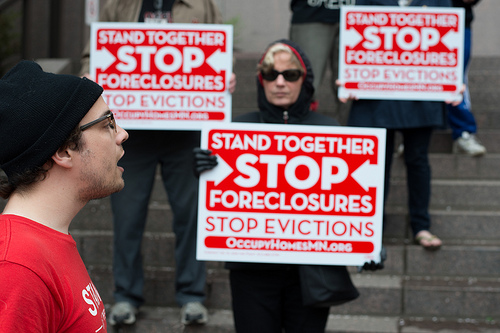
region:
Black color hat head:
[10, 65, 97, 132]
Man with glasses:
[39, 108, 136, 218]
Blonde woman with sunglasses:
[248, 43, 322, 121]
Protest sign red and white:
[202, 131, 394, 271]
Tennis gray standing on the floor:
[103, 297, 209, 322]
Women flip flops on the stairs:
[392, 216, 454, 255]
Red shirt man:
[0, 210, 110, 327]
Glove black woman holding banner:
[187, 139, 224, 191]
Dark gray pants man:
[110, 152, 200, 297]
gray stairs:
[364, 262, 497, 332]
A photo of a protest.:
[1, 0, 499, 332]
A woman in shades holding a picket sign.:
[196, 38, 388, 330]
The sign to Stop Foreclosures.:
[208, 155, 375, 242]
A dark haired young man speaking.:
[1, 60, 127, 332]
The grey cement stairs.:
[443, 197, 495, 330]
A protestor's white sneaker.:
[447, 128, 494, 167]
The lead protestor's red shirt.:
[1, 215, 123, 330]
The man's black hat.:
[2, 58, 100, 175]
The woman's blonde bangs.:
[260, 41, 295, 68]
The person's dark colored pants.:
[113, 130, 205, 330]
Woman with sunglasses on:
[241, 46, 311, 98]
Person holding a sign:
[186, 115, 458, 289]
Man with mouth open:
[55, 105, 169, 200]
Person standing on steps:
[88, 256, 220, 332]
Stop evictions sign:
[200, 192, 380, 275]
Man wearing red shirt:
[6, 203, 146, 325]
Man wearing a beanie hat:
[3, 93, 178, 206]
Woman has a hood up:
[241, 37, 354, 156]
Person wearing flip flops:
[398, 196, 463, 261]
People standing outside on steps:
[11, 61, 496, 298]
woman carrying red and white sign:
[202, 48, 397, 256]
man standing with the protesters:
[2, 62, 144, 332]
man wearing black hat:
[2, 63, 119, 331]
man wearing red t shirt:
[0, 194, 116, 328]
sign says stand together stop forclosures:
[201, 118, 391, 270]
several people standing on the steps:
[91, 3, 493, 326]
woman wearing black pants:
[206, 236, 389, 327]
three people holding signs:
[82, 14, 464, 326]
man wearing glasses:
[85, 103, 127, 138]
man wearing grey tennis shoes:
[103, 274, 216, 328]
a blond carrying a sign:
[187, 42, 392, 332]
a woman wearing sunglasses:
[190, 40, 387, 332]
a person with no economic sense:
[192, 39, 389, 331]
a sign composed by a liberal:
[197, 123, 386, 260]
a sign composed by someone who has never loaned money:
[197, 124, 387, 259]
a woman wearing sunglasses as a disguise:
[182, 41, 389, 331]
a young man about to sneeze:
[0, 70, 130, 330]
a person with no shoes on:
[408, 221, 443, 258]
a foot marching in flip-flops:
[411, 225, 442, 250]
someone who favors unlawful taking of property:
[187, 40, 385, 331]